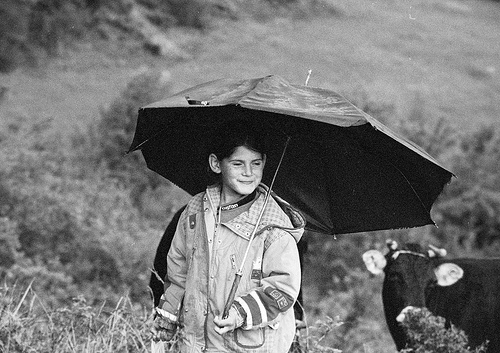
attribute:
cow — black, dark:
[363, 241, 500, 350]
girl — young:
[157, 113, 300, 353]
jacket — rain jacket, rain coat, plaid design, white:
[156, 188, 303, 352]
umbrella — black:
[133, 67, 459, 238]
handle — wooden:
[220, 272, 241, 318]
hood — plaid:
[202, 185, 310, 240]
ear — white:
[436, 259, 468, 296]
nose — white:
[392, 302, 431, 329]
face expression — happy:
[222, 149, 270, 192]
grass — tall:
[8, 1, 499, 130]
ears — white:
[361, 245, 465, 285]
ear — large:
[206, 150, 221, 175]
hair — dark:
[207, 121, 273, 158]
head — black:
[358, 233, 466, 328]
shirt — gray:
[217, 195, 263, 223]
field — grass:
[2, 3, 498, 263]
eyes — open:
[388, 268, 446, 288]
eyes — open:
[225, 156, 266, 170]